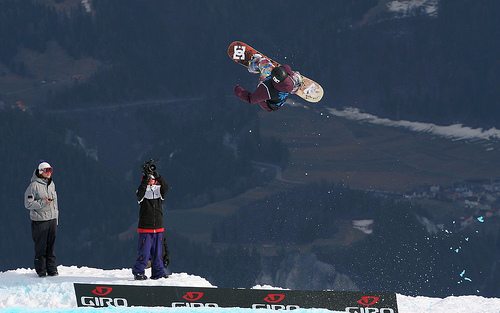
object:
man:
[233, 51, 305, 113]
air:
[2, 2, 500, 293]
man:
[133, 174, 170, 281]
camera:
[141, 157, 160, 177]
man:
[25, 161, 62, 277]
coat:
[23, 167, 61, 225]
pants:
[132, 229, 169, 277]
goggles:
[38, 168, 58, 175]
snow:
[1, 262, 493, 311]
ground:
[1, 261, 499, 311]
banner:
[70, 280, 401, 311]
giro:
[77, 283, 130, 310]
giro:
[168, 286, 222, 311]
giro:
[251, 288, 303, 312]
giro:
[341, 292, 400, 312]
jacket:
[233, 65, 303, 112]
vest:
[259, 78, 295, 114]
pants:
[245, 56, 279, 80]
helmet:
[270, 65, 290, 84]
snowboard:
[225, 38, 324, 103]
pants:
[30, 218, 59, 275]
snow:
[318, 101, 500, 152]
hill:
[0, 81, 495, 181]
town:
[400, 172, 499, 220]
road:
[20, 85, 228, 110]